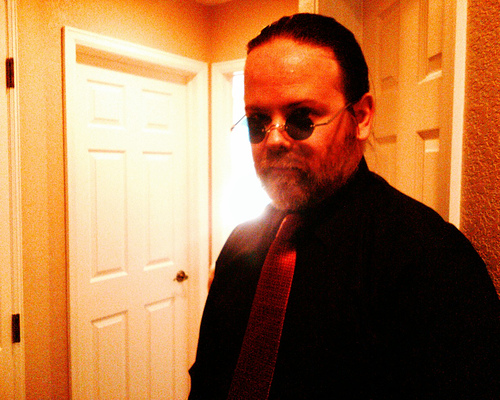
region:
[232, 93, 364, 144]
a man's black sunglasses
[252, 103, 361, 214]
a man's gray beard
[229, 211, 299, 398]
part of a red tie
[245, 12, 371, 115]
part of a man's black hair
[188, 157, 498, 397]
part of a man's black shirt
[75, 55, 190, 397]
part of a white door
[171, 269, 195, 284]
a door latch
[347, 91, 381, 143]
the ear of a man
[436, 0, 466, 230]
part of a white wall trim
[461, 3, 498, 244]
part of a textured wall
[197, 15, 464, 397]
man wearing sunglasses and a tie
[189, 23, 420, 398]
man wearing a black shirt and small sunglasses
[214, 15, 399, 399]
man looking toward the camera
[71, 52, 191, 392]
white door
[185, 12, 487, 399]
man standing in a hallway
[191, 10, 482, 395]
man with sunglasses and facial hair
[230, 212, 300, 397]
red necktie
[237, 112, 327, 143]
round sunglasses lenses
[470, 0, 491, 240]
textured wall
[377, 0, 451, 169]
door behind the man's back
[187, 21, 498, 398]
Man standing in the doorway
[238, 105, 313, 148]
Man is wearing sunglasses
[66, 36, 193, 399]
White closed door to the left of man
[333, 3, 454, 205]
Closed door behind and to the right of the man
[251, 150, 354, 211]
Man has a beard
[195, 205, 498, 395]
Man has black shirt on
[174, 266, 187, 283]
Brass handle on the door to the left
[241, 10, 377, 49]
Man has very dark hair and it's combed straight back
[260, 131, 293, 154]
Man has short and stubby nose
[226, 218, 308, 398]
man is wearing a tie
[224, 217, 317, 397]
the tie is red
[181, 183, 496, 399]
man wearing a dress shirt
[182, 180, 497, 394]
man's shirt is black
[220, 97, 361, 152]
man is wearing sunglasses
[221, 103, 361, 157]
the sunglasses are black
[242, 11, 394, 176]
man's hair is black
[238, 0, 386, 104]
man's hair is pulled back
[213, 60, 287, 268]
light shining behind the man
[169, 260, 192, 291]
door handle is brown